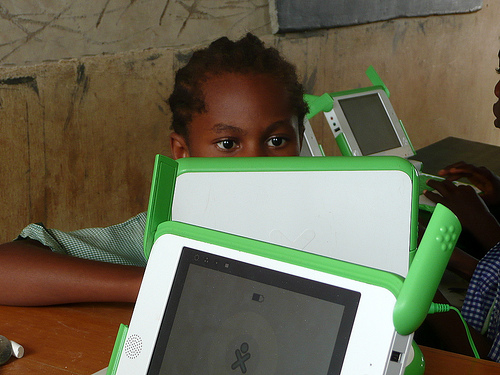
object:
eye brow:
[209, 123, 243, 133]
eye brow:
[264, 120, 293, 135]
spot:
[369, 363, 373, 368]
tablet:
[108, 218, 414, 374]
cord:
[431, 297, 483, 363]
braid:
[170, 92, 203, 107]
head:
[170, 34, 308, 161]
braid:
[173, 66, 203, 84]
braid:
[189, 52, 217, 72]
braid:
[213, 36, 235, 70]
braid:
[239, 33, 261, 64]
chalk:
[10, 340, 24, 358]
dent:
[1, 74, 41, 91]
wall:
[0, 1, 500, 245]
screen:
[273, 0, 488, 36]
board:
[1, 0, 499, 241]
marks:
[0, 0, 271, 61]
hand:
[421, 176, 500, 241]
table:
[393, 133, 498, 176]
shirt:
[19, 208, 153, 266]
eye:
[215, 137, 236, 152]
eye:
[265, 137, 284, 151]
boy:
[0, 33, 312, 305]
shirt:
[461, 244, 499, 362]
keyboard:
[417, 173, 443, 199]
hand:
[456, 164, 499, 205]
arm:
[0, 212, 147, 306]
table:
[0, 251, 500, 374]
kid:
[412, 46, 500, 359]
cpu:
[326, 63, 419, 167]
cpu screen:
[142, 246, 363, 374]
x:
[230, 351, 252, 373]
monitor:
[145, 156, 421, 284]